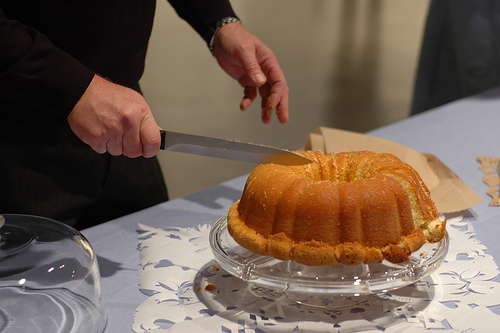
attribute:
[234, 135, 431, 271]
cake — orange, brown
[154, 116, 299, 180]
knife — silver, grey, sharp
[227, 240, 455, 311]
glass — clear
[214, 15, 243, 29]
watch — shiny, silver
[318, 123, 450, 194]
napkin — brown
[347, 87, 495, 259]
table — grey, white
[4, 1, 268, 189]
person — white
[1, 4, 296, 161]
man — white